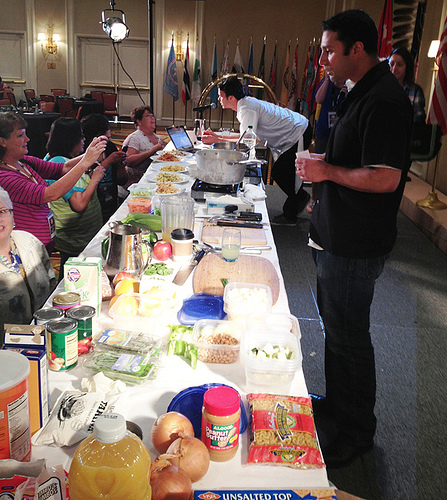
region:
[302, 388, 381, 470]
Man wearing shoes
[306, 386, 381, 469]
Man is wearing shoes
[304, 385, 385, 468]
Man wearing black shoes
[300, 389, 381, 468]
Man is wearing black shoes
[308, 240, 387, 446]
Man wearing pants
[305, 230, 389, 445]
Man is wearing pants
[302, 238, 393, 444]
Man wearing blue pants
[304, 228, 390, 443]
Man is wearing blue pants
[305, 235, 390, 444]
Man wearing blue jeans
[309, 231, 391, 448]
Man is wearing blue jeans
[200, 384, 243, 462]
jar of peanut butter on a white table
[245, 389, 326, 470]
pack of pasta on a white table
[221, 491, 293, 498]
white print on a box reading Unsalted Top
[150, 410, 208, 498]
three brown onions on a table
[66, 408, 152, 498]
bottle of orange juice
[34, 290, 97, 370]
four cans on a table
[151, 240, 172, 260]
red apple on a table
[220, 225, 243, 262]
glass on a wooden cutting board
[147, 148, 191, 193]
plates of food on a table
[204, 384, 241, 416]
red peanut butter lid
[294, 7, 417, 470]
A man wearing a black shirt.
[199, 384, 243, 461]
A jar of peanut butter.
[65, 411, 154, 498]
A bottle of juice.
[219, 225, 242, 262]
A glass of juice.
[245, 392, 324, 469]
A bag of macaroni noodles.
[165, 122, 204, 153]
A laptop on the table.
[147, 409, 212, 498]
Onions on the table.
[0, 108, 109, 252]
A woman wearing a striped shirt.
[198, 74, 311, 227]
A person wearing a white shirt.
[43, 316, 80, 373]
Canned food on a table.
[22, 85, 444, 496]
PEOPLE ARE IN A LECTURE ROOM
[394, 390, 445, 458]
the floor is grey in colour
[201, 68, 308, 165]
a person is giving a presentation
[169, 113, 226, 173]
he has a black microphone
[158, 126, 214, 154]
his laptop is on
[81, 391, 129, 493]
yellow juice in the bottle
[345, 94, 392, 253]
the shirt is black in clour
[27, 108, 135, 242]
people are taking pictures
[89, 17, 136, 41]
the light is on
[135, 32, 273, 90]
flags are near the wall